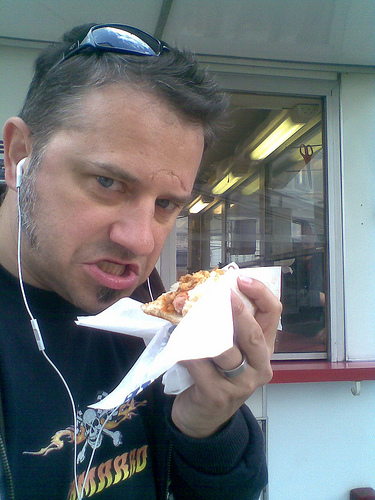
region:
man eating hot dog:
[0, 21, 282, 496]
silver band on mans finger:
[215, 353, 248, 379]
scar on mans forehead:
[149, 169, 189, 193]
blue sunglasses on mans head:
[37, 21, 174, 83]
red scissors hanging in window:
[297, 145, 315, 188]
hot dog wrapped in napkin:
[69, 261, 283, 411]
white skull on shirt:
[75, 407, 122, 463]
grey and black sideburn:
[17, 137, 49, 248]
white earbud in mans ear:
[13, 155, 28, 187]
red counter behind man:
[266, 355, 374, 382]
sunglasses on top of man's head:
[23, 18, 218, 92]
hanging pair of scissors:
[287, 143, 325, 192]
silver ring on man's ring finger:
[207, 351, 262, 386]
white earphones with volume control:
[7, 152, 59, 379]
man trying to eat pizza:
[2, 19, 296, 391]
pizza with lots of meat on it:
[141, 264, 233, 348]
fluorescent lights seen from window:
[183, 99, 320, 220]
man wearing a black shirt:
[2, 20, 276, 498]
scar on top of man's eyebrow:
[140, 157, 200, 223]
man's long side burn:
[0, 117, 69, 277]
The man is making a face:
[2, 23, 307, 498]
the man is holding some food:
[139, 266, 273, 434]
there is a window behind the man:
[175, 71, 331, 361]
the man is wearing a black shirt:
[3, 275, 272, 498]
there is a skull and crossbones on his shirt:
[68, 390, 133, 460]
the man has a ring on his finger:
[170, 276, 281, 435]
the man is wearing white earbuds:
[10, 144, 154, 498]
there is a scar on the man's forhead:
[151, 163, 189, 191]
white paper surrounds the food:
[71, 261, 287, 411]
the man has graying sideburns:
[17, 133, 40, 251]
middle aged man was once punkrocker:
[1, 16, 273, 498]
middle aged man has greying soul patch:
[94, 282, 125, 308]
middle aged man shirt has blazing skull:
[20, 393, 150, 467]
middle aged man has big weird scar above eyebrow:
[147, 165, 190, 195]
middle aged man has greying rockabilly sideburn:
[12, 140, 51, 259]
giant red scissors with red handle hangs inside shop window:
[298, 143, 317, 191]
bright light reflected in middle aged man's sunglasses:
[100, 25, 153, 53]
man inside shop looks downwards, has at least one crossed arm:
[275, 215, 329, 344]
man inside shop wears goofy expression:
[288, 217, 318, 263]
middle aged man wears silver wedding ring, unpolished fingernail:
[209, 272, 260, 381]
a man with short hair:
[3, 16, 261, 308]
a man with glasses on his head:
[1, 16, 239, 312]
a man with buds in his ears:
[2, 15, 231, 317]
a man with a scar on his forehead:
[0, 15, 231, 316]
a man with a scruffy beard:
[1, 17, 229, 342]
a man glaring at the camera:
[1, 16, 235, 318]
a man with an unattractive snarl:
[0, 15, 224, 322]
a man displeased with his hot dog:
[0, 30, 254, 369]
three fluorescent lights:
[184, 109, 315, 224]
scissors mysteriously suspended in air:
[180, 90, 330, 352]